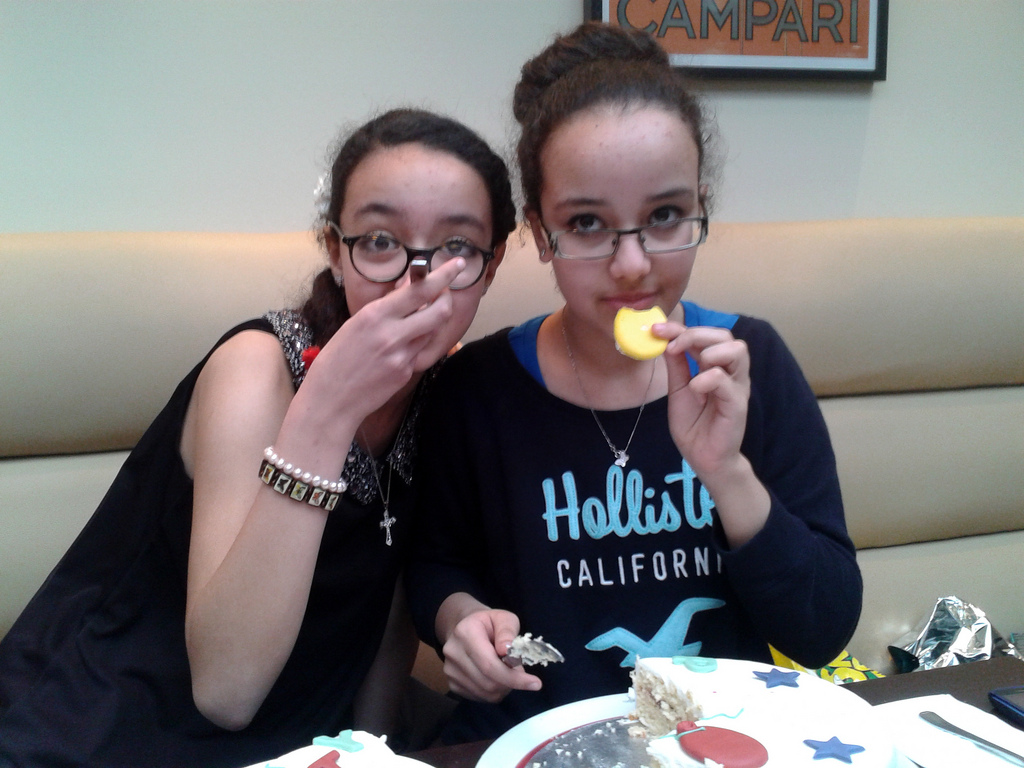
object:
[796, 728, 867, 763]
star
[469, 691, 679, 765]
plate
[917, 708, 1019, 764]
utensil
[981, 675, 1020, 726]
cell phone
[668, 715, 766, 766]
circle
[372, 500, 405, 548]
cross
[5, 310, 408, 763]
shirt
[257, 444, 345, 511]
bracelet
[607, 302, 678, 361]
knecklace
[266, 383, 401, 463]
knecklace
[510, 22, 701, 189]
hair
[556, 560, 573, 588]
letter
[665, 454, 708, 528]
letter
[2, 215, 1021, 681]
bench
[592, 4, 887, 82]
picture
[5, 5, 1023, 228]
wall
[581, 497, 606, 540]
letter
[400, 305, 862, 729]
shirt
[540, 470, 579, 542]
letter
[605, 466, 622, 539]
letter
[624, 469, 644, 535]
letter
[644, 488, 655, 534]
letter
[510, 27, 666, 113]
bun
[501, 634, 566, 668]
cake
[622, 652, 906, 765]
cake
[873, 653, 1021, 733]
table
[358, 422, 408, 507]
chain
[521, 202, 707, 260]
glasses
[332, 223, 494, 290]
glasses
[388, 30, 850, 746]
girl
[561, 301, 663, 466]
necklace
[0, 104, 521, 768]
girl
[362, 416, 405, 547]
necklace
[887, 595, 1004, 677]
paper